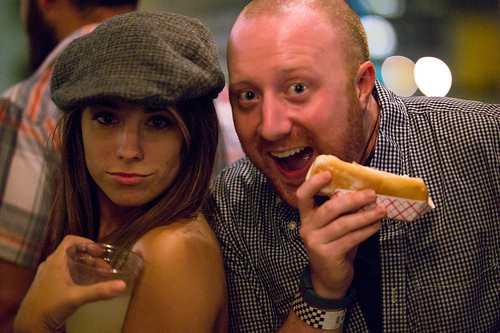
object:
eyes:
[88, 106, 177, 134]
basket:
[326, 188, 435, 222]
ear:
[354, 60, 375, 112]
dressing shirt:
[202, 94, 499, 333]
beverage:
[64, 240, 145, 333]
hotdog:
[299, 153, 427, 203]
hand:
[296, 170, 387, 301]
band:
[292, 286, 356, 331]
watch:
[298, 263, 357, 309]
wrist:
[294, 269, 354, 325]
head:
[223, 0, 376, 210]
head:
[46, 10, 224, 206]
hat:
[46, 10, 227, 111]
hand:
[14, 234, 127, 333]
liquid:
[64, 294, 130, 333]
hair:
[242, 0, 371, 77]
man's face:
[226, 42, 363, 166]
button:
[288, 221, 297, 231]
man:
[204, 0, 500, 333]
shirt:
[207, 78, 500, 333]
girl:
[8, 10, 229, 333]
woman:
[11, 10, 226, 333]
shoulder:
[128, 210, 223, 260]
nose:
[257, 88, 292, 144]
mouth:
[263, 144, 317, 181]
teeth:
[270, 145, 305, 158]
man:
[0, 1, 139, 324]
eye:
[227, 79, 262, 112]